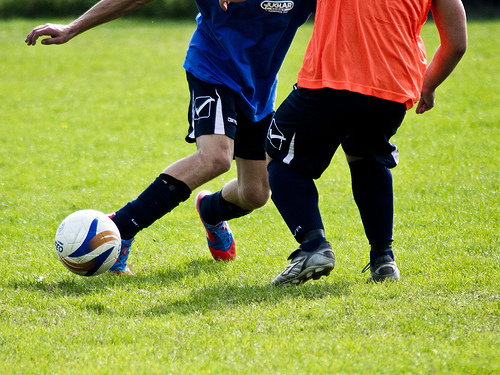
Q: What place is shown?
A: It is a field.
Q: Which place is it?
A: It is a field.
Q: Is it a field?
A: Yes, it is a field.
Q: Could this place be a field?
A: Yes, it is a field.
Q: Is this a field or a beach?
A: It is a field.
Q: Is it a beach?
A: No, it is a field.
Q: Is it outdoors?
A: Yes, it is outdoors.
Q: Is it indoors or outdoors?
A: It is outdoors.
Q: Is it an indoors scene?
A: No, it is outdoors.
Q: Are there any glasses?
A: No, there are no glasses.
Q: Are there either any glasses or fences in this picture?
A: No, there are no glasses or fences.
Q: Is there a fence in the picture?
A: No, there are no fences.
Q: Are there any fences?
A: No, there are no fences.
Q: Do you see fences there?
A: No, there are no fences.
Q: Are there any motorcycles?
A: No, there are no motorcycles.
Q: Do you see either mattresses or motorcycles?
A: No, there are no motorcycles or mattresses.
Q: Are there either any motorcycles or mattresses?
A: No, there are no motorcycles or mattresses.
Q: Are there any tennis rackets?
A: No, there are no tennis rackets.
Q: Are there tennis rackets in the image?
A: No, there are no tennis rackets.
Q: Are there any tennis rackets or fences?
A: No, there are no tennis rackets or fences.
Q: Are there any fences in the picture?
A: No, there are no fences.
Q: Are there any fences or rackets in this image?
A: No, there are no fences or rackets.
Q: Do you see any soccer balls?
A: Yes, there is a soccer ball.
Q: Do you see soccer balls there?
A: Yes, there is a soccer ball.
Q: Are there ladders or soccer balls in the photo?
A: Yes, there is a soccer ball.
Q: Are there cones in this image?
A: No, there are no cones.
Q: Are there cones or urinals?
A: No, there are no cones or urinals.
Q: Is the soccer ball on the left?
A: Yes, the soccer ball is on the left of the image.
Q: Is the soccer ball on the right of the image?
A: No, the soccer ball is on the left of the image.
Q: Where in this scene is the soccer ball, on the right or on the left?
A: The soccer ball is on the left of the image.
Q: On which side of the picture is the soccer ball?
A: The soccer ball is on the left of the image.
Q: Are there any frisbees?
A: No, there are no frisbees.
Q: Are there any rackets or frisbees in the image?
A: No, there are no frisbees or rackets.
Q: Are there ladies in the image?
A: No, there are no ladies.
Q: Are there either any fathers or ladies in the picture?
A: No, there are no ladies or fathers.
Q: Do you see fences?
A: No, there are no fences.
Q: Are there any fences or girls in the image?
A: No, there are no fences or girls.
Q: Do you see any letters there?
A: Yes, there are letters.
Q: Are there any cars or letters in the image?
A: Yes, there are letters.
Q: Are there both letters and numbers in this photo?
A: No, there are letters but no numbers.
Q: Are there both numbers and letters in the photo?
A: No, there are letters but no numbers.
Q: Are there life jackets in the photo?
A: No, there are no life jackets.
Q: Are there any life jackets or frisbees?
A: No, there are no life jackets or frisbees.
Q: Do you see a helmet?
A: No, there are no helmets.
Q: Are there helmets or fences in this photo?
A: No, there are no helmets or fences.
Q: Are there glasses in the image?
A: No, there are no glasses.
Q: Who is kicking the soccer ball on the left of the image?
A: The man is kicking the soccer ball.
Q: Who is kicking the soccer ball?
A: The man is kicking the soccer ball.